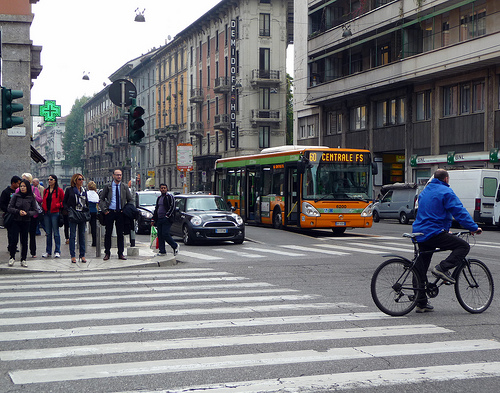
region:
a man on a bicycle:
[353, 150, 498, 332]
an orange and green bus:
[177, 128, 396, 265]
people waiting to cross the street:
[0, 157, 198, 272]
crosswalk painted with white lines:
[82, 260, 291, 384]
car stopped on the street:
[162, 157, 264, 270]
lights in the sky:
[125, 4, 160, 27]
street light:
[115, 96, 171, 168]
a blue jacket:
[402, 159, 471, 261]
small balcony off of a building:
[237, 36, 290, 88]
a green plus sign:
[29, 85, 79, 130]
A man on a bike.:
[370, 167, 495, 315]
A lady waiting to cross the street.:
[60, 171, 96, 265]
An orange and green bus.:
[211, 142, 376, 235]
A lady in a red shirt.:
[37, 172, 65, 259]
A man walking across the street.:
[149, 181, 180, 258]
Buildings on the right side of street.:
[33, 40, 498, 202]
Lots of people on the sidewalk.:
[2, 167, 180, 268]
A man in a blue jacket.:
[410, 166, 482, 314]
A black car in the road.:
[169, 193, 245, 247]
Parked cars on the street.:
[373, 168, 499, 225]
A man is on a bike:
[360, 165, 496, 330]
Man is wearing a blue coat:
[390, 170, 485, 250]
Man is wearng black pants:
[400, 226, 471, 301]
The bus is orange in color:
[210, 141, 380, 241]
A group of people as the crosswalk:
[2, 162, 177, 267]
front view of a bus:
[291, 147, 378, 234]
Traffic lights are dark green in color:
[5, 81, 156, 152]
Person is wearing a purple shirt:
[155, 191, 170, 216]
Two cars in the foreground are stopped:
[130, 181, 255, 252]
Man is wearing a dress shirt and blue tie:
[101, 163, 136, 216]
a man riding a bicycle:
[381, 151, 498, 331]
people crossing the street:
[5, 169, 195, 254]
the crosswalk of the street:
[0, 268, 412, 389]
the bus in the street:
[191, 142, 389, 242]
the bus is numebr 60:
[212, 146, 396, 238]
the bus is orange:
[201, 145, 393, 236]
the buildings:
[93, 2, 487, 143]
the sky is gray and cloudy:
[55, 17, 116, 52]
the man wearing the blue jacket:
[404, 177, 479, 241]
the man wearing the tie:
[101, 162, 139, 228]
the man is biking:
[403, 152, 470, 259]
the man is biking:
[387, 165, 464, 305]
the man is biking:
[383, 160, 497, 362]